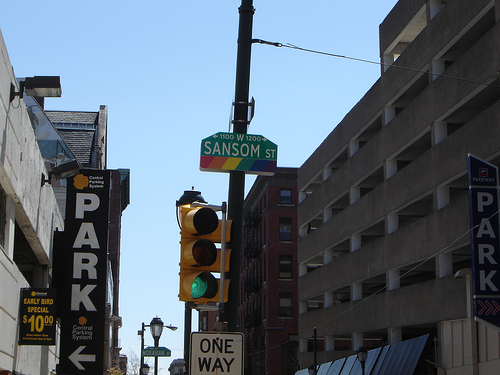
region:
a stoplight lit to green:
[165, 179, 239, 321]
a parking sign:
[60, 153, 115, 372]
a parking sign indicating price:
[12, 277, 59, 350]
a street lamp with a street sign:
[132, 303, 180, 370]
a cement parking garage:
[281, 55, 496, 367]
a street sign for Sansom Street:
[185, 106, 294, 184]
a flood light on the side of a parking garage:
[5, 58, 68, 123]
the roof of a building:
[38, 100, 118, 163]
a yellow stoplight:
[167, 179, 239, 321]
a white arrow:
[60, 342, 105, 370]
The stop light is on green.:
[171, 193, 236, 306]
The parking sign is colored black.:
[63, 164, 123, 371]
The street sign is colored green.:
[198, 132, 278, 174]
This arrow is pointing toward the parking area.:
[56, 342, 100, 373]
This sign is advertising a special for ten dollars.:
[18, 288, 57, 347]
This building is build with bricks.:
[244, 163, 299, 373]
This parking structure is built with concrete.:
[298, 87, 498, 362]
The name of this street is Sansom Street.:
[199, 135, 276, 177]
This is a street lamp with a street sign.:
[139, 317, 176, 374]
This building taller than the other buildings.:
[44, 101, 124, 169]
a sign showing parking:
[18, 158, 113, 371]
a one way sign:
[185, 327, 252, 370]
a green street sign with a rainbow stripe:
[198, 127, 283, 182]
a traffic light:
[177, 190, 234, 306]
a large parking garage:
[287, 19, 499, 369]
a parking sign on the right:
[459, 144, 498, 329]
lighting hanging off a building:
[12, 68, 58, 123]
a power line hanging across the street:
[228, 28, 499, 116]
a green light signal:
[181, 270, 236, 305]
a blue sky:
[2, 2, 414, 168]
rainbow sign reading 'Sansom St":
[200, 132, 277, 176]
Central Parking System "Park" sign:
[57, 170, 103, 373]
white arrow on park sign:
[65, 345, 97, 371]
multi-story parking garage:
[296, 0, 498, 372]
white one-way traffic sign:
[190, 331, 244, 373]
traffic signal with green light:
[179, 201, 231, 304]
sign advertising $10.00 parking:
[18, 288, 55, 343]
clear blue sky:
[0, 1, 400, 373]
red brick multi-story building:
[231, 166, 300, 373]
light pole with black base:
[149, 317, 162, 373]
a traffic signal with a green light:
[181, 202, 231, 302]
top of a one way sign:
[190, 331, 240, 373]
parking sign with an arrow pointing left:
[66, 167, 106, 373]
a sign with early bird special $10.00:
[15, 286, 58, 343]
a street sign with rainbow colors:
[201, 126, 280, 176]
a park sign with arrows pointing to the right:
[468, 150, 498, 328]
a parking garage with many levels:
[298, 95, 470, 373]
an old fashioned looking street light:
[150, 317, 165, 344]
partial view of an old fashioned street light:
[174, 186, 207, 227]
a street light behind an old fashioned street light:
[137, 318, 182, 373]